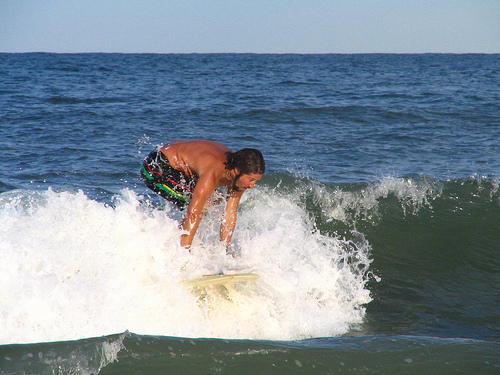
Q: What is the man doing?
A: Surfing.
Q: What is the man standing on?
A: Surfboard.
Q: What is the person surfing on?
A: Waves.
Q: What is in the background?
A: Water.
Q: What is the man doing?
A: Surfing.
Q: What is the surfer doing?
A: Surfing on a wave.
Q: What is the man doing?
A: Surfing on a wave.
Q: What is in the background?
A: A blue sky.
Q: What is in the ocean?
A: A surfer.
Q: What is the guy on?
A: A surfboard.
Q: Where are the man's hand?
A: On the surfboard.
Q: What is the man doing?
A: Surfing.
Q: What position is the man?
A: Hunched over.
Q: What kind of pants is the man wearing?
A: Shorts.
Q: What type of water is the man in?
A: Ocean.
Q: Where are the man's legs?
A: On the surfboard.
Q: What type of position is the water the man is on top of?
A: A wave.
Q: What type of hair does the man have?
A: Short.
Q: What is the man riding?
A: Surfboard.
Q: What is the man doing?
A: Surfing.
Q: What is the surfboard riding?
A: Waves.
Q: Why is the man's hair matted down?
A: Wet.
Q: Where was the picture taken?
A: Ocean.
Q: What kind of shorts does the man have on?
A: Board shorts.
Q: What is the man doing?
A: On a surfboard.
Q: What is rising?
A: A wave.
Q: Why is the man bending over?
A: Holding a board.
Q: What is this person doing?
A: Surfing.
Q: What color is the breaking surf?
A: White.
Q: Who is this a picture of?
A: Surfer.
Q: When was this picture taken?
A: Daytime.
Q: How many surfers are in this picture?
A: One.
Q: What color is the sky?
A: Blue.